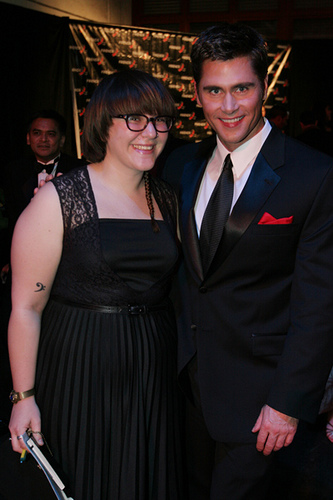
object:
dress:
[32, 162, 180, 500]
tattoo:
[34, 281, 46, 294]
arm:
[8, 182, 66, 390]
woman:
[7, 63, 181, 499]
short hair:
[80, 69, 178, 167]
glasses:
[109, 111, 174, 133]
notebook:
[9, 432, 74, 499]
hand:
[8, 395, 44, 454]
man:
[29, 22, 332, 498]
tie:
[199, 153, 234, 278]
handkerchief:
[257, 212, 293, 224]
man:
[0, 108, 91, 283]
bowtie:
[35, 160, 56, 175]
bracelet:
[9, 385, 36, 404]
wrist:
[9, 382, 37, 409]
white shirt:
[193, 116, 272, 238]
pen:
[20, 448, 26, 464]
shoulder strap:
[48, 164, 99, 228]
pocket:
[250, 222, 295, 247]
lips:
[220, 118, 247, 130]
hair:
[187, 24, 269, 91]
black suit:
[165, 126, 333, 499]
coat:
[165, 125, 332, 443]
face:
[199, 56, 262, 144]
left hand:
[251, 402, 298, 455]